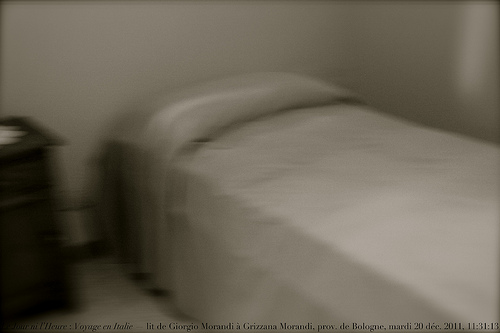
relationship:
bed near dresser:
[163, 93, 449, 222] [4, 125, 70, 251]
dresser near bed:
[4, 125, 70, 251] [163, 93, 449, 222]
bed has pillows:
[163, 93, 449, 222] [148, 70, 315, 107]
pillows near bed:
[148, 70, 315, 107] [163, 93, 449, 222]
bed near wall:
[163, 93, 449, 222] [40, 34, 93, 63]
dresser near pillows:
[4, 125, 70, 251] [148, 70, 315, 107]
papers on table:
[0, 118, 35, 142] [0, 146, 53, 257]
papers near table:
[0, 118, 35, 142] [0, 146, 53, 257]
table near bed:
[0, 146, 53, 257] [163, 93, 449, 222]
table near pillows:
[0, 146, 53, 257] [148, 70, 315, 107]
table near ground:
[0, 146, 53, 257] [97, 281, 122, 311]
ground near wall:
[97, 281, 122, 311] [40, 34, 93, 63]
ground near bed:
[97, 281, 122, 311] [163, 93, 449, 222]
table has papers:
[0, 146, 53, 257] [0, 118, 35, 142]